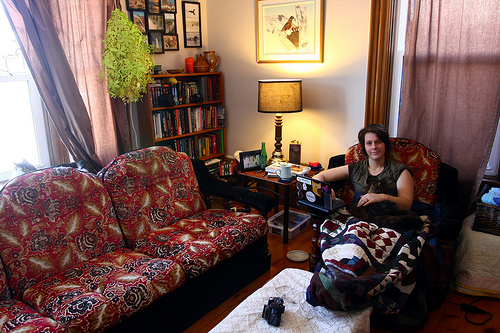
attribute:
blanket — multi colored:
[306, 203, 440, 314]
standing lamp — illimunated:
[254, 78, 304, 167]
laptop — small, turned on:
[293, 174, 351, 216]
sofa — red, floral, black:
[0, 144, 273, 331]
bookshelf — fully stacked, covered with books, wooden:
[136, 72, 227, 178]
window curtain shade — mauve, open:
[384, 1, 499, 238]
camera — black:
[259, 295, 287, 329]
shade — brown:
[257, 79, 304, 114]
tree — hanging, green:
[101, 8, 156, 150]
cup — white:
[275, 162, 296, 181]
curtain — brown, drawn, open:
[1, 3, 141, 176]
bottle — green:
[258, 139, 269, 171]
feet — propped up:
[312, 266, 362, 316]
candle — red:
[185, 57, 194, 78]